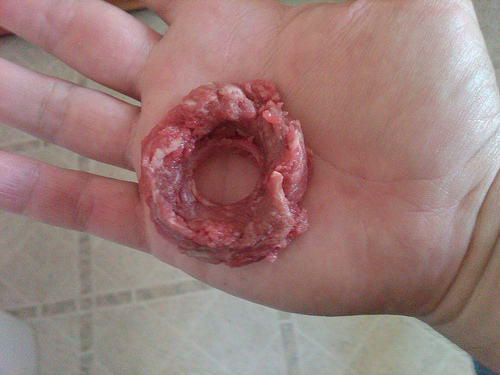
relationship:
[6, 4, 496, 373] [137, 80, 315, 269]
person holding doughnut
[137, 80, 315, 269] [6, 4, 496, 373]
doughnut in hand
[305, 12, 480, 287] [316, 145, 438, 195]
palm has arched line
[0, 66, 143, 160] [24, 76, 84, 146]
finger has lines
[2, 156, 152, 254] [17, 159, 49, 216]
finger has lines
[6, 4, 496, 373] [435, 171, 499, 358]
person seen wrist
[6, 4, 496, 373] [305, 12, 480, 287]
person seen palm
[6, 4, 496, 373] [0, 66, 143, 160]
person has finger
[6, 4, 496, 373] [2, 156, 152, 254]
person has finger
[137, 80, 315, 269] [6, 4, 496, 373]
doughnut on hand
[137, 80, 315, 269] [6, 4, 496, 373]
doughnut in photo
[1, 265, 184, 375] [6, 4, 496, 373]
tiles in photo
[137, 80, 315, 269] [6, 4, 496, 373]
doughnut in open arm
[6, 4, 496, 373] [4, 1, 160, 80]
person has finger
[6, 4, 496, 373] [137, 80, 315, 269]
person holds doughnut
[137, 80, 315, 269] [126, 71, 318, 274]
doughnut like doughnut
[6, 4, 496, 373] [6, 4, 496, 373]
hand in photo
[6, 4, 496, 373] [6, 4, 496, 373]
person in photo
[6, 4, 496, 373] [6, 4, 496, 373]
person has hand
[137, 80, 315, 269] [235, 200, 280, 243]
doughnut seen piece